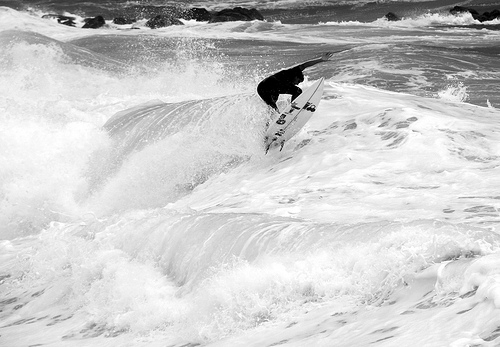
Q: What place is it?
A: It is an ocean.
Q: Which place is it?
A: It is an ocean.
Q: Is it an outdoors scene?
A: Yes, it is outdoors.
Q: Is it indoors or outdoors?
A: It is outdoors.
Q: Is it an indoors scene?
A: No, it is outdoors.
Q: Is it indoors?
A: No, it is outdoors.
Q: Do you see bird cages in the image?
A: No, there are no bird cages.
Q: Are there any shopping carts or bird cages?
A: No, there are no bird cages or shopping carts.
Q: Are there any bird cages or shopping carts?
A: No, there are no bird cages or shopping carts.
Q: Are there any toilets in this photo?
A: No, there are no toilets.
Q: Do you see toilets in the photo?
A: No, there are no toilets.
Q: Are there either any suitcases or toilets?
A: No, there are no toilets or suitcases.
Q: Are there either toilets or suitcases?
A: No, there are no toilets or suitcases.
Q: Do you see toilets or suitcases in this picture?
A: No, there are no toilets or suitcases.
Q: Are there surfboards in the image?
A: Yes, there is a surfboard.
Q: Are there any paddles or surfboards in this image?
A: Yes, there is a surfboard.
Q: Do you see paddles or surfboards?
A: Yes, there is a surfboard.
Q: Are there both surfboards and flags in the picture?
A: No, there is a surfboard but no flags.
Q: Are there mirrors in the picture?
A: No, there are no mirrors.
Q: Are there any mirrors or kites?
A: No, there are no mirrors or kites.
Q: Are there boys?
A: No, there are no boys.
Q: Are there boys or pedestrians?
A: No, there are no boys or pedestrians.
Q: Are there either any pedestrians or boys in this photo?
A: No, there are no boys or pedestrians.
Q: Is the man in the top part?
A: Yes, the man is in the top of the image.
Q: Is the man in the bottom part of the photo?
A: No, the man is in the top of the image.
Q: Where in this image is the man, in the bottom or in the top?
A: The man is in the top of the image.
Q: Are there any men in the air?
A: Yes, there is a man in the air.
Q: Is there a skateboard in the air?
A: No, there is a man in the air.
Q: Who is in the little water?
A: The man is in the water.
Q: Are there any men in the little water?
A: Yes, there is a man in the water.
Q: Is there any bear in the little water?
A: No, there is a man in the water.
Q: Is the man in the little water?
A: Yes, the man is in the water.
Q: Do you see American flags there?
A: No, there are no American flags.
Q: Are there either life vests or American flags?
A: No, there are no American flags or life vests.